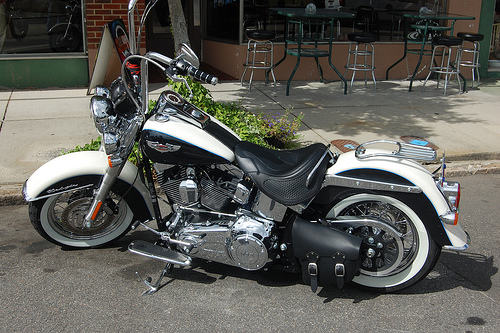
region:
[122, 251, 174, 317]
kick stand on a motorcycle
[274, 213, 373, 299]
saddle bag on a motorcycle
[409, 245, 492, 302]
shadow of a motorcycle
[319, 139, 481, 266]
rear fender of the motorcycle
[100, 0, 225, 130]
a set of handlebars on a cycle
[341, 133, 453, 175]
a rack on the back fender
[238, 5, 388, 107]
a metal and chairs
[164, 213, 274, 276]
chrome covered cycle part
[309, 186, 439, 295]
a white sidewall tire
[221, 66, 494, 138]
the shadow of a tree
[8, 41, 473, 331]
white and black Harley-Davidson motorcycle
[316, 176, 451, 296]
white wall tire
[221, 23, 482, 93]
black cushioned and chrome stools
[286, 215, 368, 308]
black double buckled saddle bag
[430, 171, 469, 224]
chrome tail light and turn signals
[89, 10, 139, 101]
windshield for motorcycle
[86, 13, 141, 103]
side view of a sandwich board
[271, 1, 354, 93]
green metal patio table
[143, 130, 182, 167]
Logo for Harley-Davidson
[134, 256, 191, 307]
chrome kickstand rests on pavement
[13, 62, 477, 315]
a white and black motorcycle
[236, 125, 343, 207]
a black seat on a motorcycle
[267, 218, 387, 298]
a black saddle bag on a motorcycle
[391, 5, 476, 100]
outdoor dining table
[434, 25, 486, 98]
two bar stools with black seats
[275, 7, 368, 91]
a green eating table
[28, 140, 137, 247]
a white front fender on a motorcycle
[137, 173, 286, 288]
chrome engine on a motorcycle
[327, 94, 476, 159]
concrete side walk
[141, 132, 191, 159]
metal emblem on a motorcycle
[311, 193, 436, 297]
the back tire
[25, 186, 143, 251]
front tire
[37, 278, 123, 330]
the street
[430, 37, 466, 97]
the stool is black and grey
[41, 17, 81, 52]
reflection of the motorcycle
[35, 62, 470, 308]
a motorcycle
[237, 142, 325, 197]
the seat is black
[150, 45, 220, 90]
the handlebar of the motorcycle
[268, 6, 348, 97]
a table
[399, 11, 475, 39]
the table is green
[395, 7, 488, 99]
right bistro table near wall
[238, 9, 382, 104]
left bistro table and stools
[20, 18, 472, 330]
white motorcycle parked at curb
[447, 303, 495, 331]
dirty black spot on street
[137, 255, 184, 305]
silver metal kick stand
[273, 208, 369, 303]
black leather saddle bag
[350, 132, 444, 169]
silver metal luggage rack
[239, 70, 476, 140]
shadow of tree canopy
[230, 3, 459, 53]
window of business in background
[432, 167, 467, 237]
silver and orange cycle tail light